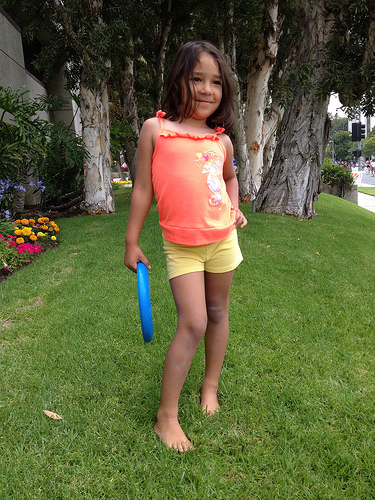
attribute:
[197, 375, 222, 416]
foot — grass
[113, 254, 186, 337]
frisbee — blue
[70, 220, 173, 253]
hand — her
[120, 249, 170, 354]
frisbee — blue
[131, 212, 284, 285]
shorts — yellow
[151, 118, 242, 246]
tank — pink, top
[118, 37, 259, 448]
girl — posing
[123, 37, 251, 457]
girl — little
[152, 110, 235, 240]
shirt — sea horse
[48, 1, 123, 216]
tree — green, brushy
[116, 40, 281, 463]
girl — young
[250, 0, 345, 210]
tree — gray, black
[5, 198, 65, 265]
flowers — pink, yellow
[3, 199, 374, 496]
grass — green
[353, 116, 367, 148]
street light — black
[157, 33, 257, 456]
girls — small